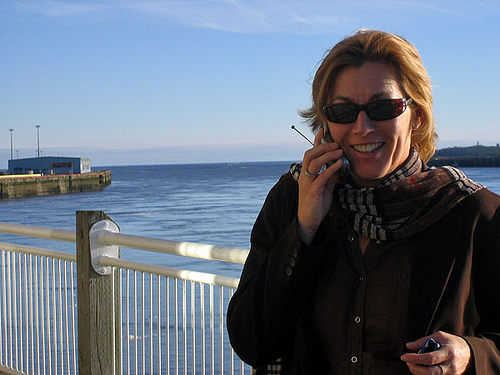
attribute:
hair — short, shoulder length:
[296, 27, 443, 164]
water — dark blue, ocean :
[126, 154, 298, 185]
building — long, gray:
[5, 152, 92, 179]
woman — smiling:
[278, 31, 453, 373]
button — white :
[350, 274, 365, 281]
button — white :
[349, 310, 361, 323]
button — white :
[343, 353, 363, 362]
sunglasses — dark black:
[315, 90, 416, 122]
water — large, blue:
[104, 139, 284, 290]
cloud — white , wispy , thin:
[193, 7, 285, 34]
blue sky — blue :
[67, 39, 214, 122]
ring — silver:
[439, 362, 445, 373]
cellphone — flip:
[317, 135, 349, 179]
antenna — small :
[281, 111, 315, 151]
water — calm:
[1, 161, 497, 373]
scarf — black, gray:
[283, 144, 434, 235]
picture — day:
[6, 0, 498, 370]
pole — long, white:
[128, 227, 185, 271]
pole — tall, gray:
[71, 210, 129, 374]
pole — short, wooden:
[84, 204, 115, 372]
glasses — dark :
[318, 94, 416, 126]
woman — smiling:
[226, 28, 498, 373]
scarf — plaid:
[286, 148, 485, 242]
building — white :
[2, 144, 99, 183]